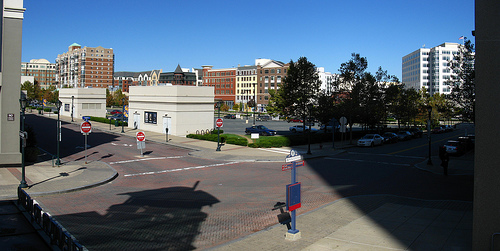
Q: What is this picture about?
A: City.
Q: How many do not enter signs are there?
A: 3.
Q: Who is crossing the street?
A: 1 person.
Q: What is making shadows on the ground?
A: Tall buildings.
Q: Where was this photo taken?
A: Corner of the street.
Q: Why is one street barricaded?
A: One way street.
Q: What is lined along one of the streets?
A: Vehicles.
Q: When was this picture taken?
A: During the day.